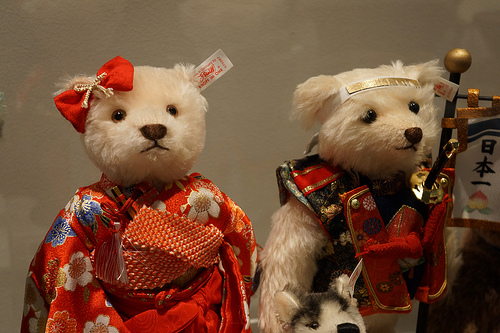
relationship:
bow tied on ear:
[51, 54, 137, 136] [50, 71, 101, 96]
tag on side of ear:
[189, 46, 235, 94] [174, 60, 204, 92]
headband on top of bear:
[333, 75, 429, 110] [252, 54, 465, 332]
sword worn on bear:
[406, 136, 461, 218] [252, 54, 465, 332]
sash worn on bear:
[100, 265, 238, 332] [16, 45, 265, 331]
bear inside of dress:
[16, 45, 265, 331] [19, 173, 262, 333]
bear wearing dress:
[16, 45, 265, 331] [19, 173, 262, 333]